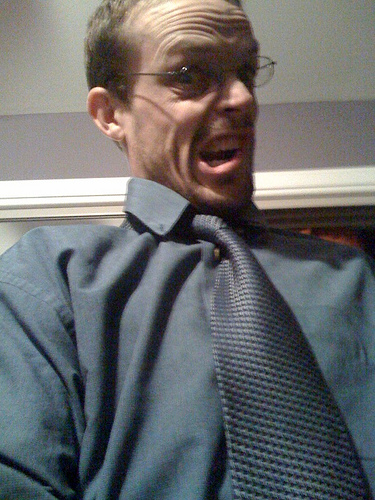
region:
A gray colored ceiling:
[279, 3, 374, 99]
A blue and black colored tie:
[211, 268, 363, 496]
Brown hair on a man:
[85, 0, 128, 88]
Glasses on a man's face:
[115, 53, 277, 95]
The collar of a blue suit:
[119, 176, 185, 237]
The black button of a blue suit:
[208, 244, 227, 264]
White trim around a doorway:
[1, 173, 125, 220]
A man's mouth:
[198, 128, 254, 175]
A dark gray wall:
[2, 118, 86, 175]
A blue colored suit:
[9, 201, 373, 498]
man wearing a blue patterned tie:
[177, 211, 370, 489]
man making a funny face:
[197, 125, 255, 171]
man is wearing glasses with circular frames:
[107, 58, 312, 103]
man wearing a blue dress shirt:
[6, 181, 372, 490]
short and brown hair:
[72, 0, 159, 103]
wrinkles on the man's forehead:
[157, 9, 264, 56]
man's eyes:
[162, 54, 288, 98]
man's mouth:
[194, 127, 258, 173]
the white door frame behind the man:
[2, 166, 372, 251]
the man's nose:
[211, 72, 270, 112]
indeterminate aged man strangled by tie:
[0, 0, 373, 498]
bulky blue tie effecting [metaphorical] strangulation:
[180, 207, 372, 497]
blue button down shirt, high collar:
[0, 173, 374, 497]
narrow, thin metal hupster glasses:
[109, 52, 279, 93]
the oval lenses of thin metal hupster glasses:
[177, 54, 277, 93]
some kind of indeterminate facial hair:
[125, 110, 257, 213]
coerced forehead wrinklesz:
[134, 2, 261, 56]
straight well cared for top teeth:
[202, 134, 243, 155]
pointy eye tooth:
[210, 138, 220, 151]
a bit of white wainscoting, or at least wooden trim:
[0, 163, 373, 244]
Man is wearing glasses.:
[110, 46, 281, 103]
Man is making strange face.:
[78, 1, 289, 219]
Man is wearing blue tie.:
[187, 212, 373, 498]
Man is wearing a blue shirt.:
[1, 176, 373, 499]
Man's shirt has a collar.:
[112, 167, 280, 252]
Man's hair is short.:
[79, 1, 259, 152]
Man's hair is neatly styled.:
[77, 0, 281, 147]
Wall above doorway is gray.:
[0, 94, 373, 181]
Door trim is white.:
[0, 164, 372, 227]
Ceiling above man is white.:
[1, 0, 374, 121]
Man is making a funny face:
[98, 6, 309, 209]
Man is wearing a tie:
[201, 208, 370, 498]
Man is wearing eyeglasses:
[154, 51, 315, 108]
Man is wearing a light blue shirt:
[0, 197, 372, 493]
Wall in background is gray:
[0, 16, 367, 155]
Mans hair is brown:
[64, 0, 155, 98]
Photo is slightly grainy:
[6, 12, 366, 488]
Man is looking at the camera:
[66, 6, 300, 210]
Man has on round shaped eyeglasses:
[124, 48, 293, 97]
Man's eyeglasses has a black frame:
[112, 51, 314, 100]